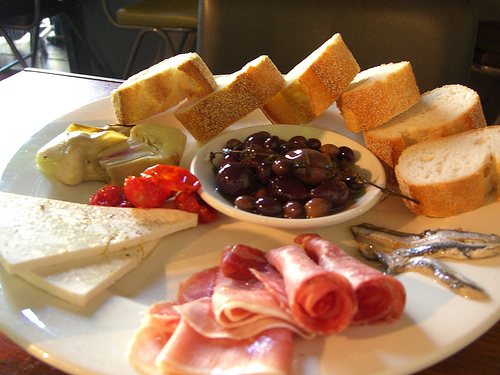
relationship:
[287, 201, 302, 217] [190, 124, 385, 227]
olive in dish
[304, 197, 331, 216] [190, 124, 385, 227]
olive in dish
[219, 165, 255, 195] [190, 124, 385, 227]
olive in dish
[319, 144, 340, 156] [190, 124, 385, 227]
olive in dish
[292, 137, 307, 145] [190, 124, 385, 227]
olive in dish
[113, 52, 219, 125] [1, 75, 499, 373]
slice of bread on top of dish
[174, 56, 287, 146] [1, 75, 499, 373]
slice of bread on top of dish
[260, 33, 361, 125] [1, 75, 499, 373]
slice of bread on top of dish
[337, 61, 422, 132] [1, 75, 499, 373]
slice of bread on top of dish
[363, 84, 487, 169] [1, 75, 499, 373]
slice of bread on top of dish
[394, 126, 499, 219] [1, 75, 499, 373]
slice of bread on top of dish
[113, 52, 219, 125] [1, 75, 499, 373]
slice of bread on top fo dish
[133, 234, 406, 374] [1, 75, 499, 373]
meat on dish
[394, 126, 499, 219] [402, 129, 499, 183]
slice of bread has inside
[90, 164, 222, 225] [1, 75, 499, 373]
fruit on top of dish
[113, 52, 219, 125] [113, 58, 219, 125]
slice of bread has crust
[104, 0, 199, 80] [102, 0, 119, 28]
chair has back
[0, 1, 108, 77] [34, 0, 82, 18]
chair has back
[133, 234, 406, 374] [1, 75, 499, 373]
meat on top of dish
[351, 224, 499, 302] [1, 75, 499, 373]
sardines on top of dish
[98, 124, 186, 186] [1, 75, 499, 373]
mushroom on top of dish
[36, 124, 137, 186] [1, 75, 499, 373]
mushroom on top of dish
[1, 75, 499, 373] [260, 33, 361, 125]
dish holds slice of bread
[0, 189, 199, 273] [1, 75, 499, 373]
cheese on top of dish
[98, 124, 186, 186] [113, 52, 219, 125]
mushroom next to slice of bread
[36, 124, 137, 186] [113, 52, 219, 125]
mushroom next to slice of bread